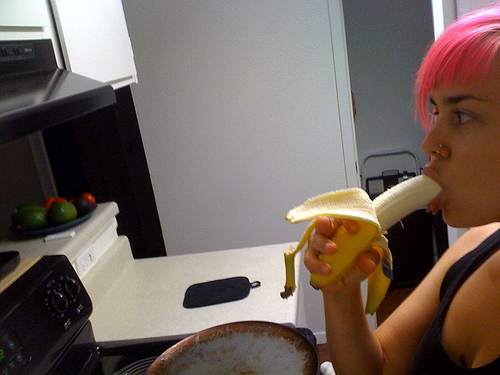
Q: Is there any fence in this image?
A: No, there are no fences.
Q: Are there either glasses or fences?
A: No, there are no fences or glasses.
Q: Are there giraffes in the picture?
A: No, there are no giraffes.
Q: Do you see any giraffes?
A: No, there are no giraffes.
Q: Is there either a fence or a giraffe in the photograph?
A: No, there are no giraffes or fences.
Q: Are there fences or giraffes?
A: No, there are no giraffes or fences.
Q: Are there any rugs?
A: No, there are no rugs.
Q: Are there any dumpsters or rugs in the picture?
A: No, there are no rugs or dumpsters.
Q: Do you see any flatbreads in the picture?
A: No, there are no flatbreads.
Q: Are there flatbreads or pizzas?
A: No, there are no flatbreads or pizzas.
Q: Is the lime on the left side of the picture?
A: Yes, the lime is on the left of the image.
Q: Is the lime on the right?
A: No, the lime is on the left of the image.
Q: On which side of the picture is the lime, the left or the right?
A: The lime is on the left of the image.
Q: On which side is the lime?
A: The lime is on the left of the image.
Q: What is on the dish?
A: The lime is on the dish.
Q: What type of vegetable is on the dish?
A: The vegetable is a lime.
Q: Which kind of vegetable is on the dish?
A: The vegetable is a lime.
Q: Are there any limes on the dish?
A: Yes, there is a lime on the dish.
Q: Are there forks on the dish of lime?
A: No, there is a lime on the dish.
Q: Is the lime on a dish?
A: Yes, the lime is on a dish.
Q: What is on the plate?
A: The lime is on the plate.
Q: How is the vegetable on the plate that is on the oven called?
A: The vegetable is a lime.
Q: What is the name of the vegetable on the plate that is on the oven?
A: The vegetable is a lime.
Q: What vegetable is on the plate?
A: The vegetable is a lime.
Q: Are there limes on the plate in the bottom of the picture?
A: Yes, there is a lime on the plate.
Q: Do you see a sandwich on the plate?
A: No, there is a lime on the plate.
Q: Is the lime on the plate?
A: Yes, the lime is on the plate.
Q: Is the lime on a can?
A: No, the lime is on the plate.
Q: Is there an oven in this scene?
A: Yes, there is an oven.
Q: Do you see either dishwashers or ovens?
A: Yes, there is an oven.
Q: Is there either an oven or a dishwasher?
A: Yes, there is an oven.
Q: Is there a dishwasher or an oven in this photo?
A: Yes, there is an oven.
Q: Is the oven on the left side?
A: Yes, the oven is on the left of the image.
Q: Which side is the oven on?
A: The oven is on the left of the image.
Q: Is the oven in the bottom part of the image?
A: Yes, the oven is in the bottom of the image.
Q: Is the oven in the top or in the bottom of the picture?
A: The oven is in the bottom of the image.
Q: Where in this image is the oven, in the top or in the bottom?
A: The oven is in the bottom of the image.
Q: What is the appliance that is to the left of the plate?
A: The appliance is an oven.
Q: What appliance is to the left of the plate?
A: The appliance is an oven.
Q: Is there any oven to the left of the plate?
A: Yes, there is an oven to the left of the plate.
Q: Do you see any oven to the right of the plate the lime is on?
A: No, the oven is to the left of the plate.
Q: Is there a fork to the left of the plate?
A: No, there is an oven to the left of the plate.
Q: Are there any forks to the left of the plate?
A: No, there is an oven to the left of the plate.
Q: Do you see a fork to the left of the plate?
A: No, there is an oven to the left of the plate.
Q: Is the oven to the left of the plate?
A: Yes, the oven is to the left of the plate.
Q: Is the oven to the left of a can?
A: No, the oven is to the left of the plate.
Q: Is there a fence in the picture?
A: No, there are no fences.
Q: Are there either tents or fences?
A: No, there are no fences or tents.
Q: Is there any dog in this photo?
A: No, there are no dogs.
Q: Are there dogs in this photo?
A: No, there are no dogs.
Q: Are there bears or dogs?
A: No, there are no dogs or bears.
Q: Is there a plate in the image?
A: Yes, there is a plate.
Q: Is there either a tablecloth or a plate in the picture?
A: Yes, there is a plate.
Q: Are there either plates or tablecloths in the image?
A: Yes, there is a plate.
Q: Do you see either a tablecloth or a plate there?
A: Yes, there is a plate.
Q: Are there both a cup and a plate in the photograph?
A: No, there is a plate but no cups.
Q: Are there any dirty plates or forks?
A: Yes, there is a dirty plate.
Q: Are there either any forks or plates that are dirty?
A: Yes, the plate is dirty.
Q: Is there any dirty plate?
A: Yes, there is a dirty plate.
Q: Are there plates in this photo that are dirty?
A: Yes, there is a plate that is dirty.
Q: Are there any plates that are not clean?
A: Yes, there is a dirty plate.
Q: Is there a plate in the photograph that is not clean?
A: Yes, there is a dirty plate.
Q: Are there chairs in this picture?
A: No, there are no chairs.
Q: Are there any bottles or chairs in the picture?
A: No, there are no chairs or bottles.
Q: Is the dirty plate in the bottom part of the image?
A: Yes, the plate is in the bottom of the image.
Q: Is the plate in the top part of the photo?
A: No, the plate is in the bottom of the image.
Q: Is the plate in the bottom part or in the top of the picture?
A: The plate is in the bottom of the image.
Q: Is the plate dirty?
A: Yes, the plate is dirty.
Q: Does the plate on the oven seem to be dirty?
A: Yes, the plate is dirty.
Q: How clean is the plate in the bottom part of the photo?
A: The plate is dirty.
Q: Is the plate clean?
A: No, the plate is dirty.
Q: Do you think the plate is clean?
A: No, the plate is dirty.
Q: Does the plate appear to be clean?
A: No, the plate is dirty.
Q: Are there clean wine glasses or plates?
A: No, there is a plate but it is dirty.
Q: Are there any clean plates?
A: No, there is a plate but it is dirty.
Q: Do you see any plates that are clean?
A: No, there is a plate but it is dirty.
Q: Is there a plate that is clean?
A: No, there is a plate but it is dirty.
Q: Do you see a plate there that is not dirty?
A: No, there is a plate but it is dirty.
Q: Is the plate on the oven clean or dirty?
A: The plate is dirty.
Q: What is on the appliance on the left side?
A: The plate is on the oven.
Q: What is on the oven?
A: The plate is on the oven.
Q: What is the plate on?
A: The plate is on the oven.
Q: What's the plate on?
A: The plate is on the oven.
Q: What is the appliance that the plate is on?
A: The appliance is an oven.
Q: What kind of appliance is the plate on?
A: The plate is on the oven.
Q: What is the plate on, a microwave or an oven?
A: The plate is on an oven.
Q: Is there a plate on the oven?
A: Yes, there is a plate on the oven.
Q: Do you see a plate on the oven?
A: Yes, there is a plate on the oven.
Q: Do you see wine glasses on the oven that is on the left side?
A: No, there is a plate on the oven.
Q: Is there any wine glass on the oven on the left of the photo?
A: No, there is a plate on the oven.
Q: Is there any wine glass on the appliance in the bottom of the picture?
A: No, there is a plate on the oven.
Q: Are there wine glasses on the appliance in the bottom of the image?
A: No, there is a plate on the oven.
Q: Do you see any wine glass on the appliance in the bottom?
A: No, there is a plate on the oven.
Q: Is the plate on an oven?
A: Yes, the plate is on an oven.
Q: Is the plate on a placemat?
A: No, the plate is on an oven.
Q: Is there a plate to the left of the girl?
A: Yes, there is a plate to the left of the girl.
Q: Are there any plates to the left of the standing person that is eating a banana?
A: Yes, there is a plate to the left of the girl.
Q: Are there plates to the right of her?
A: No, the plate is to the left of the girl.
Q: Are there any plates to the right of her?
A: No, the plate is to the left of the girl.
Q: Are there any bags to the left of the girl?
A: No, there is a plate to the left of the girl.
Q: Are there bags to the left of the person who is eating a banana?
A: No, there is a plate to the left of the girl.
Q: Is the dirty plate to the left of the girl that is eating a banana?
A: Yes, the plate is to the left of the girl.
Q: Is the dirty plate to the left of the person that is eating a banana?
A: Yes, the plate is to the left of the girl.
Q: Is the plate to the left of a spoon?
A: No, the plate is to the left of the girl.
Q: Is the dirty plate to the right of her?
A: No, the plate is to the left of the girl.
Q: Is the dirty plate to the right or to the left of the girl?
A: The plate is to the left of the girl.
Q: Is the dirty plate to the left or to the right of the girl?
A: The plate is to the left of the girl.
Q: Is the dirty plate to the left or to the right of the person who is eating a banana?
A: The plate is to the left of the girl.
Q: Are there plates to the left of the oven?
A: No, the plate is to the right of the oven.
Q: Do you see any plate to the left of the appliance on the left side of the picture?
A: No, the plate is to the right of the oven.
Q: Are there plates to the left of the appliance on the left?
A: No, the plate is to the right of the oven.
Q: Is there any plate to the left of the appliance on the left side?
A: No, the plate is to the right of the oven.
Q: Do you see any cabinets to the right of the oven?
A: No, there is a plate to the right of the oven.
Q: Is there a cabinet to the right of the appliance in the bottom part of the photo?
A: No, there is a plate to the right of the oven.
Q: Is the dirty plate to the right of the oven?
A: Yes, the plate is to the right of the oven.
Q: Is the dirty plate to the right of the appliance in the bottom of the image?
A: Yes, the plate is to the right of the oven.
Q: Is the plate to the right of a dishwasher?
A: No, the plate is to the right of the oven.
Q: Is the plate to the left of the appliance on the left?
A: No, the plate is to the right of the oven.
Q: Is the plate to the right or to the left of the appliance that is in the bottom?
A: The plate is to the right of the oven.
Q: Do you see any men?
A: No, there are no men.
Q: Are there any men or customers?
A: No, there are no men or customers.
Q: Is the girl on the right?
A: Yes, the girl is on the right of the image.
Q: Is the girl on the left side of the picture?
A: No, the girl is on the right of the image.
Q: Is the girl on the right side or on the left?
A: The girl is on the right of the image.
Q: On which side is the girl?
A: The girl is on the right of the image.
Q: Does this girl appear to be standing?
A: Yes, the girl is standing.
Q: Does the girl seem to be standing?
A: Yes, the girl is standing.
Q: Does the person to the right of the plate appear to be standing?
A: Yes, the girl is standing.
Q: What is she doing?
A: The girl is standing.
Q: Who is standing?
A: The girl is standing.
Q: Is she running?
A: No, the girl is standing.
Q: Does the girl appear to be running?
A: No, the girl is standing.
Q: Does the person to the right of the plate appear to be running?
A: No, the girl is standing.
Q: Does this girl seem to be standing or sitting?
A: The girl is standing.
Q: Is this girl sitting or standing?
A: The girl is standing.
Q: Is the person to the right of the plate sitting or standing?
A: The girl is standing.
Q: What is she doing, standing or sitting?
A: The girl is standing.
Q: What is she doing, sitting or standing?
A: The girl is standing.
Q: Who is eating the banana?
A: The girl is eating the banana.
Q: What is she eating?
A: The girl is eating a banana.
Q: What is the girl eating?
A: The girl is eating a banana.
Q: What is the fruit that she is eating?
A: The fruit is a banana.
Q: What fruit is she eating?
A: The girl is eating a banana.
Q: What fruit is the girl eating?
A: The girl is eating a banana.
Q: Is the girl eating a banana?
A: Yes, the girl is eating a banana.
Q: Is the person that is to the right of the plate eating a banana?
A: Yes, the girl is eating a banana.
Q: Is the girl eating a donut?
A: No, the girl is eating a banana.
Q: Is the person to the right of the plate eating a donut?
A: No, the girl is eating a banana.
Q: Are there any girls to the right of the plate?
A: Yes, there is a girl to the right of the plate.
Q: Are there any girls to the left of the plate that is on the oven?
A: No, the girl is to the right of the plate.